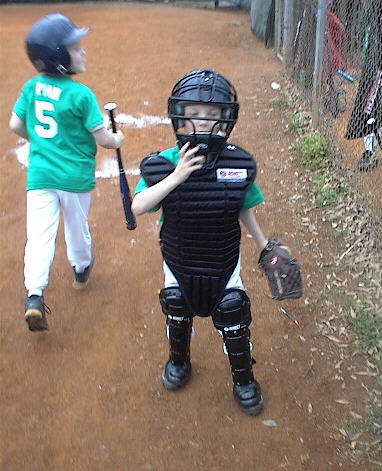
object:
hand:
[176, 140, 205, 186]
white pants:
[22, 189, 93, 293]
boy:
[10, 12, 126, 331]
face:
[185, 104, 222, 135]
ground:
[0, 0, 382, 471]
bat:
[102, 101, 136, 231]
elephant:
[128, 67, 301, 418]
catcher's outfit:
[139, 142, 302, 417]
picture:
[0, 0, 381, 469]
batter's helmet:
[24, 10, 89, 77]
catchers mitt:
[257, 236, 303, 302]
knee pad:
[209, 288, 252, 330]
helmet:
[166, 68, 238, 172]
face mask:
[165, 68, 240, 171]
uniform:
[9, 71, 105, 194]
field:
[0, 0, 382, 471]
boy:
[130, 67, 291, 416]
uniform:
[133, 145, 264, 227]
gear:
[168, 69, 241, 174]